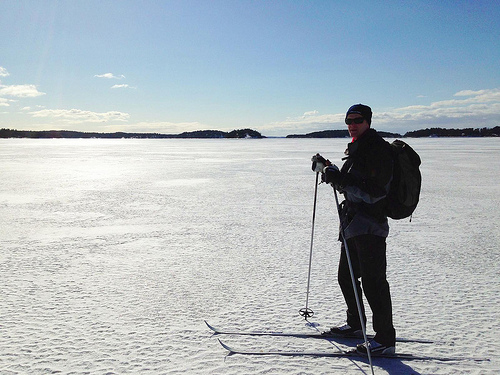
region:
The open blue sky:
[174, 13, 410, 76]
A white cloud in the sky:
[25, 99, 127, 122]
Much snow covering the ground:
[46, 151, 264, 353]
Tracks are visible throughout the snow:
[22, 220, 259, 367]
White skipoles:
[292, 160, 332, 322]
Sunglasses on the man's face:
[339, 113, 370, 129]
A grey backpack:
[382, 133, 432, 221]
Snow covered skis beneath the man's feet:
[206, 317, 461, 369]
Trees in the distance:
[411, 121, 497, 138]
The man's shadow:
[358, 326, 403, 373]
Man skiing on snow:
[199, 101, 487, 366]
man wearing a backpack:
[303, 100, 423, 364]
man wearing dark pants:
[309, 99, 419, 358]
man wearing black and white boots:
[296, 103, 433, 365]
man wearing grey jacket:
[306, 103, 427, 361]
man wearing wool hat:
[303, 100, 432, 360]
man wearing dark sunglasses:
[310, 100, 424, 360]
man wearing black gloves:
[308, 101, 424, 361]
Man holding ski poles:
[303, 103, 415, 364]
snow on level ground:
[2, 139, 495, 372]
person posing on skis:
[207, 94, 429, 361]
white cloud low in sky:
[55, 95, 130, 133]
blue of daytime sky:
[349, 10, 451, 70]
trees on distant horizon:
[170, 126, 257, 142]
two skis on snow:
[197, 320, 317, 360]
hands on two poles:
[292, 161, 362, 360]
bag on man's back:
[375, 132, 429, 217]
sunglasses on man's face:
[337, 114, 367, 131]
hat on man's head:
[350, 102, 379, 122]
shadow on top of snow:
[368, 350, 420, 370]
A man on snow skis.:
[202, 102, 492, 372]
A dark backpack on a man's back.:
[388, 139, 422, 221]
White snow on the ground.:
[1, 135, 498, 370]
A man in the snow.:
[311, 102, 396, 357]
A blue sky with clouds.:
[3, 0, 495, 137]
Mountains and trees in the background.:
[1, 126, 498, 138]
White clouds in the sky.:
[3, 66, 498, 136]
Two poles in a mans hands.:
[298, 152, 374, 374]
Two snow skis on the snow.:
[203, 317, 491, 363]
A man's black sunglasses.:
[345, 115, 369, 125]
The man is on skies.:
[202, 92, 459, 373]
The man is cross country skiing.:
[195, 97, 460, 371]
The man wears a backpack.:
[357, 130, 429, 233]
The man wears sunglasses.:
[336, 107, 373, 129]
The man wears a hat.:
[340, 95, 386, 127]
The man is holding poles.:
[297, 149, 388, 374]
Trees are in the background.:
[0, 122, 499, 147]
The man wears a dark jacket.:
[314, 127, 401, 240]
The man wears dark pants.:
[323, 219, 412, 343]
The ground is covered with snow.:
[0, 137, 498, 373]